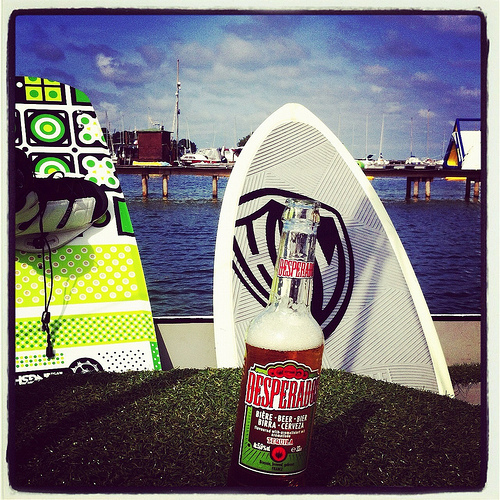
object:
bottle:
[221, 189, 327, 496]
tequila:
[225, 335, 325, 492]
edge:
[260, 99, 317, 120]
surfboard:
[209, 99, 459, 404]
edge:
[16, 70, 87, 95]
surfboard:
[13, 65, 163, 388]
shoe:
[12, 143, 110, 242]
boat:
[174, 145, 237, 167]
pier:
[105, 158, 483, 207]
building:
[133, 125, 175, 165]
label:
[241, 367, 322, 413]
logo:
[230, 186, 358, 343]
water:
[107, 164, 480, 321]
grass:
[11, 362, 491, 493]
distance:
[17, 10, 491, 213]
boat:
[98, 109, 136, 165]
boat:
[128, 156, 178, 168]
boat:
[355, 109, 397, 172]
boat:
[385, 117, 436, 171]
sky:
[16, 16, 483, 164]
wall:
[144, 310, 486, 414]